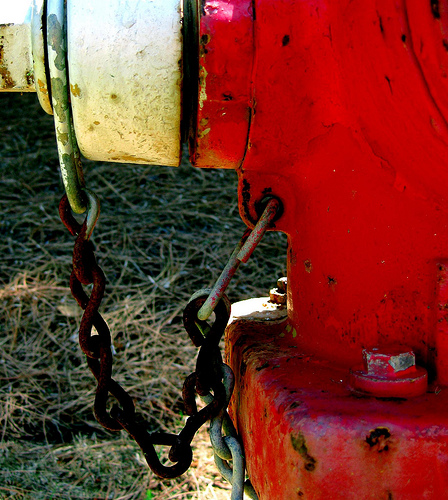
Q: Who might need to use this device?
A: A fireman.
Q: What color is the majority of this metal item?
A: Red.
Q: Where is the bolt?
A: On the front and to the right.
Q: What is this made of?
A: Metal.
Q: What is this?
A: Fire Hydrant.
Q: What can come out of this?
A: Water.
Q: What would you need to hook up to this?
A: A hose.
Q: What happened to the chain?
A: It rusted.